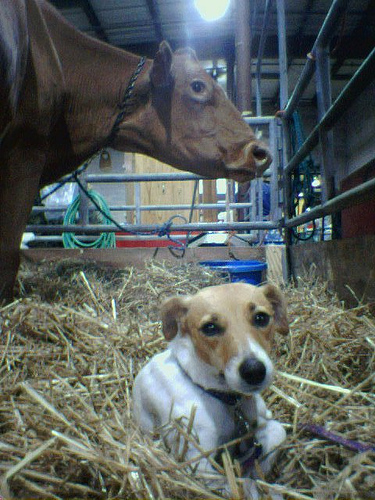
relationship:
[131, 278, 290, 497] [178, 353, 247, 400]
animal wears collar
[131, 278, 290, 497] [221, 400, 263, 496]
animal wears leash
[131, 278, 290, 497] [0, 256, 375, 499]
animal on hay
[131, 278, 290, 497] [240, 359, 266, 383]
animal has nose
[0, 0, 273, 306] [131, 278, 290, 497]
cow behind animal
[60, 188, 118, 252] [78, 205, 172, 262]
hose on railing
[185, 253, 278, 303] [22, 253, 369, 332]
bucket near straw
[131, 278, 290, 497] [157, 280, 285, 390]
animal has head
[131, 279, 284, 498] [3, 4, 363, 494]
animal in pen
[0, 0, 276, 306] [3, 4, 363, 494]
cow in pen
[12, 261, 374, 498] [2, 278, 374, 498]
stack of hay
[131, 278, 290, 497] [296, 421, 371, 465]
animal has leash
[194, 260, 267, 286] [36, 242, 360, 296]
bucket in a pen